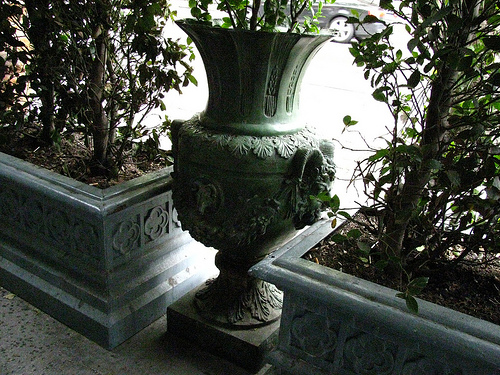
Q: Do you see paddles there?
A: No, there are no paddles.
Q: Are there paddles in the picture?
A: No, there are no paddles.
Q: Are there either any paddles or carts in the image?
A: No, there are no paddles or carts.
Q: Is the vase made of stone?
A: Yes, the vase is made of stone.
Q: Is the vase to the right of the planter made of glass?
A: No, the vase is made of stone.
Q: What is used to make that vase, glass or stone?
A: The vase is made of stone.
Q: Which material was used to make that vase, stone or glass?
A: The vase is made of stone.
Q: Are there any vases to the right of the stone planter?
A: Yes, there is a vase to the right of the planter.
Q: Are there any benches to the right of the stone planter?
A: No, there is a vase to the right of the planter.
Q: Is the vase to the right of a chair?
A: No, the vase is to the right of a planter.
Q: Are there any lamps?
A: No, there are no lamps.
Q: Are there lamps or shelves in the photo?
A: No, there are no lamps or shelves.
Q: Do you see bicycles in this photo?
A: No, there are no bicycles.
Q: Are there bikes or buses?
A: No, there are no bikes or buses.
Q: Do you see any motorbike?
A: No, there are no motorcycles.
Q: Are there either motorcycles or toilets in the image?
A: No, there are no motorcycles or toilets.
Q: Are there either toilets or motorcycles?
A: No, there are no motorcycles or toilets.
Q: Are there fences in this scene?
A: No, there are no fences.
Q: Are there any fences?
A: No, there are no fences.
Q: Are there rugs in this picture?
A: No, there are no rugs.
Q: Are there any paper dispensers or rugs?
A: No, there are no rugs or paper dispensers.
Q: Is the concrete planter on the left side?
A: Yes, the planter is on the left of the image.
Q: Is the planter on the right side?
A: No, the planter is on the left of the image.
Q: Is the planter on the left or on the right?
A: The planter is on the left of the image.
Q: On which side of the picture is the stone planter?
A: The planter is on the left of the image.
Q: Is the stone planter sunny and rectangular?
A: Yes, the planter is sunny and rectangular.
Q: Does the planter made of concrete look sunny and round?
A: No, the planter is sunny but rectangular.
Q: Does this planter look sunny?
A: Yes, the planter is sunny.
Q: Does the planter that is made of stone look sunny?
A: Yes, the planter is sunny.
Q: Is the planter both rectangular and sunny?
A: Yes, the planter is rectangular and sunny.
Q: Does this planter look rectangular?
A: Yes, the planter is rectangular.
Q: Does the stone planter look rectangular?
A: Yes, the planter is rectangular.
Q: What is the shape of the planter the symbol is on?
A: The planter is rectangular.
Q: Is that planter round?
A: No, the planter is rectangular.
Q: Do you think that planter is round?
A: No, the planter is rectangular.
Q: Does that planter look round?
A: No, the planter is rectangular.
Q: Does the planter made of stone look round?
A: No, the planter is rectangular.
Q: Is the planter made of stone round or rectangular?
A: The planter is rectangular.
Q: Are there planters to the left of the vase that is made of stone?
A: Yes, there is a planter to the left of the vase.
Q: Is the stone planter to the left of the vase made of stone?
A: Yes, the planter is to the left of the vase.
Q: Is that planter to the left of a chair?
A: No, the planter is to the left of the vase.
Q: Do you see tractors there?
A: No, there are no tractors.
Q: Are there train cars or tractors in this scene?
A: No, there are no tractors or train cars.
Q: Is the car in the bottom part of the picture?
A: No, the car is in the top of the image.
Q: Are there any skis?
A: No, there are no skis.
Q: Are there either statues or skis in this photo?
A: No, there are no skis or statues.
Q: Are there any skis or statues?
A: No, there are no skis or statues.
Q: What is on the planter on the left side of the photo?
A: The symbol is on the planter.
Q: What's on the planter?
A: The symbol is on the planter.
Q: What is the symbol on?
A: The symbol is on the planter.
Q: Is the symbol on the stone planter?
A: Yes, the symbol is on the planter.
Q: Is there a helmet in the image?
A: No, there are no helmets.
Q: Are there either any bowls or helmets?
A: No, there are no helmets or bowls.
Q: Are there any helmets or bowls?
A: No, there are no helmets or bowls.